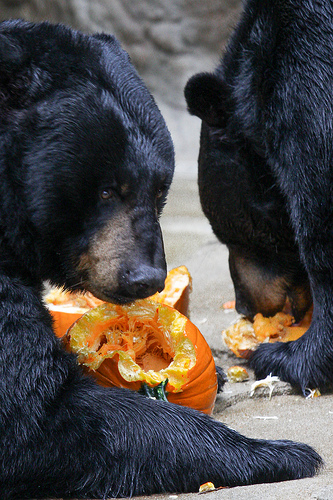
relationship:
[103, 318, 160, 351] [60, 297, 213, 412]
stuff attached to pumpkin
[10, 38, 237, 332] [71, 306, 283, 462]
bear with pumpkin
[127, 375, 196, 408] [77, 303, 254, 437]
stem on pumpkin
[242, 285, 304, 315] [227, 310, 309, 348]
mouth on pumpkin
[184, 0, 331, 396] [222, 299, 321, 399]
bear eating pumpkin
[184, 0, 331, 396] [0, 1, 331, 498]
bear at zoo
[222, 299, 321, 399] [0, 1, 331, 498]
pumpkin at zoo